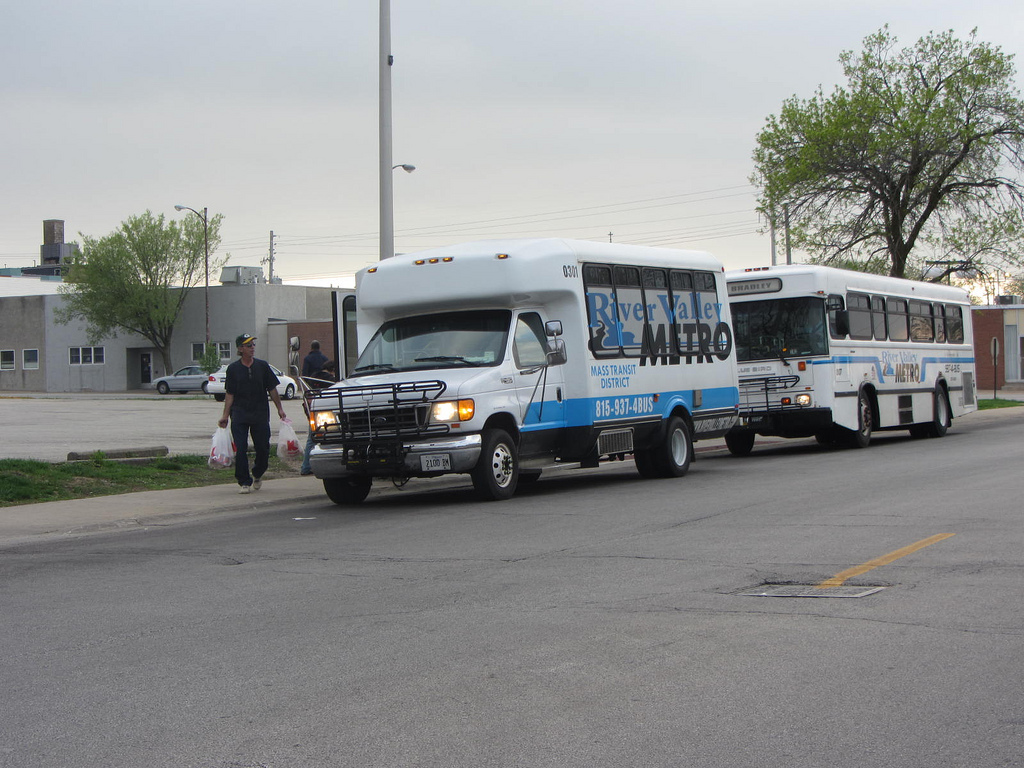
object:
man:
[217, 333, 286, 494]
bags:
[276, 421, 304, 456]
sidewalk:
[0, 395, 1022, 549]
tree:
[50, 208, 231, 377]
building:
[0, 220, 358, 394]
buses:
[304, 237, 740, 508]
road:
[0, 408, 1022, 768]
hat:
[235, 334, 257, 347]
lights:
[432, 398, 476, 422]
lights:
[781, 393, 809, 405]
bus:
[725, 265, 977, 456]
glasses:
[239, 343, 255, 347]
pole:
[380, 0, 396, 263]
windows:
[69, 346, 105, 365]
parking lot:
[0, 391, 334, 464]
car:
[151, 365, 219, 395]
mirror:
[835, 308, 849, 335]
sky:
[0, 0, 1022, 308]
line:
[814, 533, 954, 591]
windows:
[844, 289, 964, 345]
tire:
[471, 427, 520, 501]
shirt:
[225, 357, 282, 424]